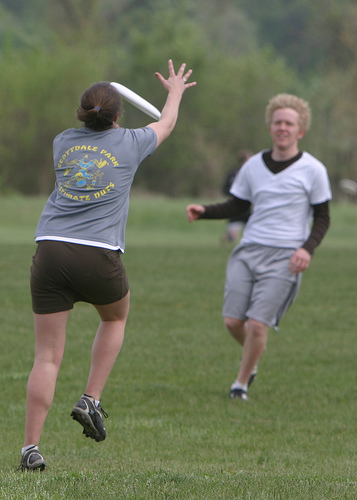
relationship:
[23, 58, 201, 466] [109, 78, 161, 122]
person playing with frisbee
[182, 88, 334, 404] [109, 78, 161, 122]
man playing with frisbee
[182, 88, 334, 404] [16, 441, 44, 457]
man wearing socks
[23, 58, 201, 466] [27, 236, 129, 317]
person wearing shorts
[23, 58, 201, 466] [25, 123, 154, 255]
person wearing shirt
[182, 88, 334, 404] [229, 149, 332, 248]
man wearing shirt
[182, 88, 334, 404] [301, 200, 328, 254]
man wearing sleeve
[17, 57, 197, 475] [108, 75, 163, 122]
woman catching frisbee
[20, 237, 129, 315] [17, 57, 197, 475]
brown shorts on woman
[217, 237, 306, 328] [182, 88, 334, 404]
shorts on man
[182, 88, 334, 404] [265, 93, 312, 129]
man with hair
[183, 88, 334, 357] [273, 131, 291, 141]
man smiling at woman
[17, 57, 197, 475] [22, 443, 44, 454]
woman wearing sock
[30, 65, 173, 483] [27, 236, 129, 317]
woman wearing shorts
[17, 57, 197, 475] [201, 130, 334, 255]
woman wearing shirt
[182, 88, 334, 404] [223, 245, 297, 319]
man wearing shorts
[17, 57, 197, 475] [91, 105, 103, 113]
woman used band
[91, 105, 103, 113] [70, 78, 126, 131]
band to tie hair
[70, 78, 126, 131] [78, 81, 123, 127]
hair in hair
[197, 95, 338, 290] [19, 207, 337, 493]
boy in field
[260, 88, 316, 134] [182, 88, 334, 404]
hair of man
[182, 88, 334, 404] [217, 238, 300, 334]
man wearing shorts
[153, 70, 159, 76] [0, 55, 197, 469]
fingernail of woman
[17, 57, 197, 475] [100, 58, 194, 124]
woman playing frisbee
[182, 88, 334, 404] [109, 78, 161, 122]
man playing frisbee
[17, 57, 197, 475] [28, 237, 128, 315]
woman wearing brown shorts